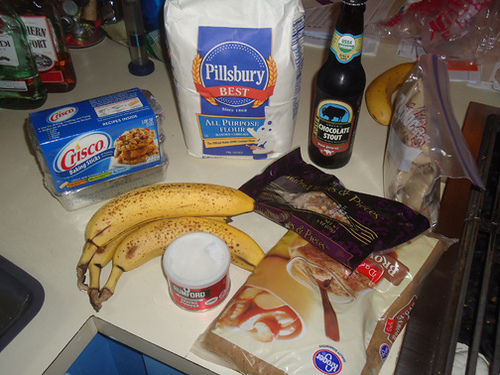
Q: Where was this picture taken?
A: In a kitchen.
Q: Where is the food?
A: On a countertop.